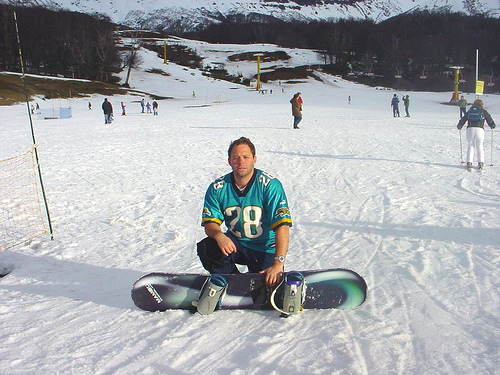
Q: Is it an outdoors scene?
A: Yes, it is outdoors.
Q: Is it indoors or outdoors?
A: It is outdoors.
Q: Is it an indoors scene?
A: No, it is outdoors.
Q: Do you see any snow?
A: Yes, there is snow.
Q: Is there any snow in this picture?
A: Yes, there is snow.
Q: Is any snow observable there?
A: Yes, there is snow.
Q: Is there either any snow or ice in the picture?
A: Yes, there is snow.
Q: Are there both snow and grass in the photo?
A: Yes, there are both snow and grass.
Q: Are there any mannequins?
A: No, there are no mannequins.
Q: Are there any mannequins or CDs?
A: No, there are no mannequins or cds.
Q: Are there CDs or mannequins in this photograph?
A: No, there are no mannequins or cds.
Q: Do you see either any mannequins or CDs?
A: No, there are no mannequins or cds.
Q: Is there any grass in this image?
A: Yes, there is grass.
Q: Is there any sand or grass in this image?
A: Yes, there is grass.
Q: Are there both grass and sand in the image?
A: No, there is grass but no sand.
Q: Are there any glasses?
A: No, there are no glasses.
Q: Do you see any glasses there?
A: No, there are no glasses.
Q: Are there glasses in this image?
A: No, there are no glasses.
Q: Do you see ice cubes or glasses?
A: No, there are no glasses or ice cubes.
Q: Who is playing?
A: The people are playing.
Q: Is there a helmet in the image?
A: No, there are no helmets.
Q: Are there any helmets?
A: No, there are no helmets.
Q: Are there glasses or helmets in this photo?
A: No, there are no helmets or glasses.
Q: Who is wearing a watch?
A: The man is wearing a watch.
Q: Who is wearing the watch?
A: The man is wearing a watch.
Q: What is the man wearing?
A: The man is wearing a watch.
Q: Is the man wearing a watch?
A: Yes, the man is wearing a watch.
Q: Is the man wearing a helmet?
A: No, the man is wearing a watch.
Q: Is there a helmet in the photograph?
A: No, there are no helmets.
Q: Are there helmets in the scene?
A: No, there are no helmets.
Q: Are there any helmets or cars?
A: No, there are no helmets or cars.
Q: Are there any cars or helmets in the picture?
A: No, there are no helmets or cars.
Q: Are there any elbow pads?
A: No, there are no elbow pads.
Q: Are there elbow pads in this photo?
A: No, there are no elbow pads.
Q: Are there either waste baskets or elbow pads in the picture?
A: No, there are no elbow pads or waste baskets.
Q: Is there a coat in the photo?
A: Yes, there is a coat.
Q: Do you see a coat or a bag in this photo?
A: Yes, there is a coat.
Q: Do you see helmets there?
A: No, there are no helmets.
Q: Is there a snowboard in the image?
A: Yes, there is a snowboard.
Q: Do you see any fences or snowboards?
A: Yes, there is a snowboard.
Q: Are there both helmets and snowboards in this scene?
A: No, there is a snowboard but no helmets.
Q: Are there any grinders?
A: No, there are no grinders.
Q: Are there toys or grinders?
A: No, there are no grinders or toys.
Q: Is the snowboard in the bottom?
A: Yes, the snowboard is in the bottom of the image.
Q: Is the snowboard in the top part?
A: No, the snowboard is in the bottom of the image.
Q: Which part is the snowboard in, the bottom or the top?
A: The snowboard is in the bottom of the image.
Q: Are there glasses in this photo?
A: No, there are no glasses.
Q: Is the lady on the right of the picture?
A: Yes, the lady is on the right of the image.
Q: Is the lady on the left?
A: No, the lady is on the right of the image.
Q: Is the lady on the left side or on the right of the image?
A: The lady is on the right of the image.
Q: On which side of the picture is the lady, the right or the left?
A: The lady is on the right of the image.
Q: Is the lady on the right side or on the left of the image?
A: The lady is on the right of the image.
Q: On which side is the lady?
A: The lady is on the right of the image.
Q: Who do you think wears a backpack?
A: The lady wears a backpack.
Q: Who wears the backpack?
A: The lady wears a backpack.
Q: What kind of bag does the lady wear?
A: The lady wears a backpack.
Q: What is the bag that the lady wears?
A: The bag is a backpack.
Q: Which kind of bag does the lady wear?
A: The lady wears a backpack.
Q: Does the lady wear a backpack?
A: Yes, the lady wears a backpack.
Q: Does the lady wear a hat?
A: No, the lady wears a backpack.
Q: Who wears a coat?
A: The lady wears a coat.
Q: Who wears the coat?
A: The lady wears a coat.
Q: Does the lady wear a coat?
A: Yes, the lady wears a coat.